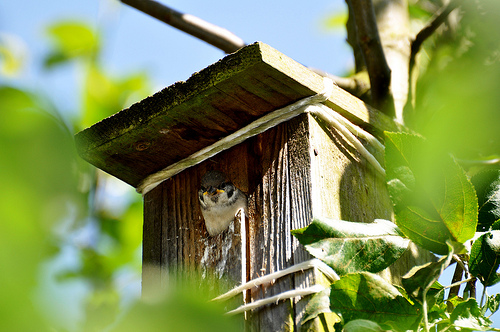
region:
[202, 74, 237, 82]
edge of a roof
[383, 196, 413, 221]
edge of a leaf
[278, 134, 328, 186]
edge of a house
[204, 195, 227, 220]
chest of a bird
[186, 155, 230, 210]
head of a bird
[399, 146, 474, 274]
Green leaf on tree.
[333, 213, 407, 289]
Green leaf on tree.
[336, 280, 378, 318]
Green leaf on tree.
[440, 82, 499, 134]
Green leaf on tree.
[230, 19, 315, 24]
Sky is clear and blue.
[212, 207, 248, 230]
Bird has white chest.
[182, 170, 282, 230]
Bird is poking head out of house.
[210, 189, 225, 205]
Bird has dark beak.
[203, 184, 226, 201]
Bird has orange markings on face.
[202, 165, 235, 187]
Bird has dark head.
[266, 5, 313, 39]
this is the sky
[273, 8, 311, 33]
the sky is blue in color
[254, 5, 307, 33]
the sky has some clouds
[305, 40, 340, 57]
the clouds are white in color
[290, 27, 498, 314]
this is a tree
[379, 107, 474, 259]
these are some leaves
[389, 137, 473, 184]
the leaves are green in color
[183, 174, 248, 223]
this is a bird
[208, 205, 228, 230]
the feathers are white in color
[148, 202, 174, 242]
this is a nest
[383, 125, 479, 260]
Green leaf on a tree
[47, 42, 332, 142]
Wooden top of a bird house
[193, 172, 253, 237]
Bird's head in a bird house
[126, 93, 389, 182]
Twine around a bird house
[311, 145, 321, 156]
Nail on the side of a bird house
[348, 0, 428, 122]
Tree trunk behind a bird house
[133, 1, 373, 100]
Tree limb behind a bird house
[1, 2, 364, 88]
Blue sky above a bird house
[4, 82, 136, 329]
Blurred leaves on a tree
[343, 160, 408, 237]
Shadow of leaves on a bird house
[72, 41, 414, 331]
A wood birdhouse in the leaves.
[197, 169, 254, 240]
A bird sticking out of a birdhouse.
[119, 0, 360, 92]
Thin branch sticking out over top of a birdhouse roof.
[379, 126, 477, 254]
Completely visible green leaf to the right of a birdhouse.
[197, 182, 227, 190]
Black small eyes of a bird.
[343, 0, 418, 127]
Thick tree trunk behind a birdhouse.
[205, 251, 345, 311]
White rope around the bottom of a birdhouse.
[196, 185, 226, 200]
Yellow and dark gray beak of a bird.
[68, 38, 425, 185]
Thick roof on a birdhouse.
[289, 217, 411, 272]
Green leaf with sun shining on it that is touching the birdhouse on the side.